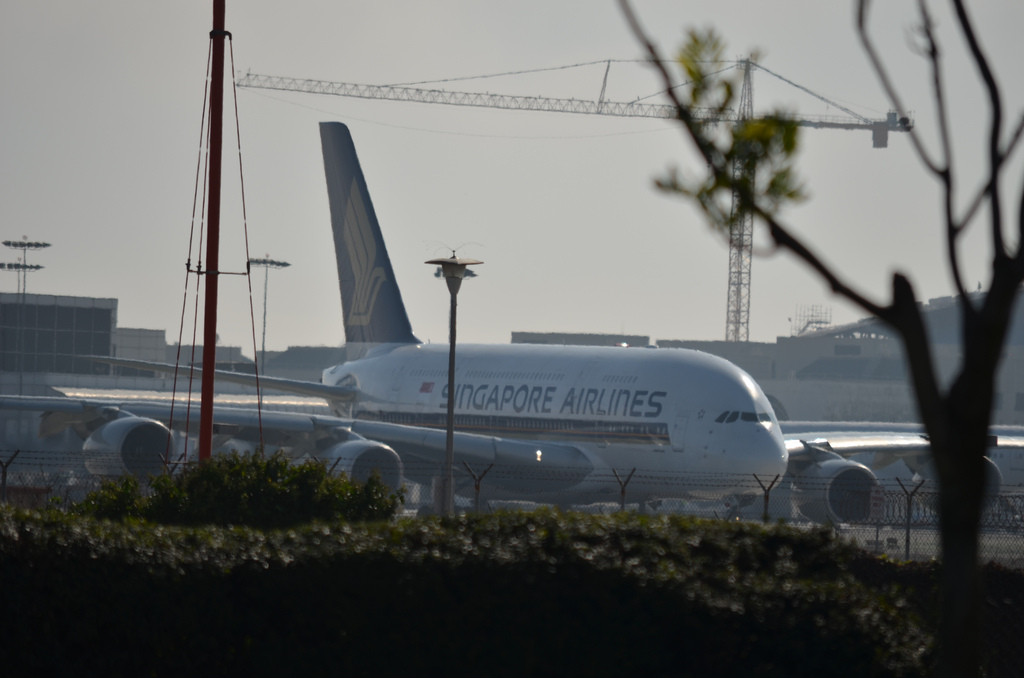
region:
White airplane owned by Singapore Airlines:
[0, 113, 1022, 525]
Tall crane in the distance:
[229, 48, 918, 336]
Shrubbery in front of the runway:
[10, 489, 991, 676]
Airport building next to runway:
[0, 301, 118, 445]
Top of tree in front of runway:
[627, 4, 1019, 673]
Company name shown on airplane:
[433, 377, 683, 417]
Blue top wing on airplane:
[320, 124, 416, 349]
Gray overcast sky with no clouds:
[1, 2, 1017, 329]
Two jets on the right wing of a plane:
[81, 417, 415, 509]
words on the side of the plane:
[392, 366, 724, 436]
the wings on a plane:
[3, 306, 655, 488]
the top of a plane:
[436, 324, 803, 402]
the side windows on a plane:
[482, 398, 669, 474]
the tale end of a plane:
[234, 129, 523, 452]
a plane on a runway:
[296, 208, 987, 576]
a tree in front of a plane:
[651, 142, 1018, 655]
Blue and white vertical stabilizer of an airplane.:
[317, 112, 423, 346]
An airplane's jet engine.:
[793, 448, 886, 537]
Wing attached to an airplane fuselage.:
[0, 372, 590, 481]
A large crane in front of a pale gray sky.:
[231, 47, 917, 339]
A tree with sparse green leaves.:
[620, 5, 1017, 663]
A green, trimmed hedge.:
[6, 501, 1000, 669]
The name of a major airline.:
[436, 375, 670, 427]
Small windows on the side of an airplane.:
[456, 416, 660, 437]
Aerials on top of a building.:
[0, 227, 141, 379]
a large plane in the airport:
[50, 111, 1022, 649]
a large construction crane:
[259, 40, 908, 364]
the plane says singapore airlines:
[62, 146, 897, 583]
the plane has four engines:
[92, 378, 1006, 544]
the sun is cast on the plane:
[138, 211, 1023, 570]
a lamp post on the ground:
[436, 228, 493, 558]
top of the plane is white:
[397, 347, 704, 404]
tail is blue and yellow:
[329, 146, 391, 361]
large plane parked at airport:
[7, 100, 1022, 543]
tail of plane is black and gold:
[310, 114, 422, 350]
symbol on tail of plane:
[330, 182, 382, 331]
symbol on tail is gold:
[327, 179, 401, 331]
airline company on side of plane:
[439, 371, 670, 429]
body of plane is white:
[303, 318, 795, 515]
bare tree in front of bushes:
[620, 3, 1020, 674]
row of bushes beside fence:
[3, 464, 1021, 670]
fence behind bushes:
[4, 431, 1014, 564]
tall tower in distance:
[711, 50, 797, 361]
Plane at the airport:
[87, 186, 980, 561]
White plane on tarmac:
[69, 179, 967, 544]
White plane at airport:
[92, 152, 990, 564]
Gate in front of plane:
[22, 429, 1018, 570]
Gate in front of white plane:
[10, 432, 1016, 582]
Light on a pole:
[427, 241, 508, 564]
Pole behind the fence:
[411, 240, 481, 529]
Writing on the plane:
[411, 363, 702, 436]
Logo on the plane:
[321, 183, 407, 365]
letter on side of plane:
[641, 380, 674, 429]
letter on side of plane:
[610, 386, 634, 421]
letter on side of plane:
[601, 386, 618, 418]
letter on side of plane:
[593, 382, 616, 417]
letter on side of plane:
[580, 386, 601, 416]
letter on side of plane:
[571, 386, 588, 409]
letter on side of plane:
[540, 379, 561, 418]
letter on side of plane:
[508, 382, 534, 414]